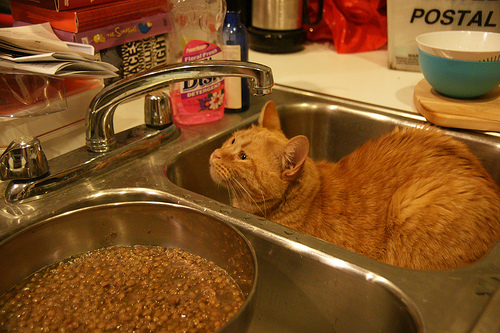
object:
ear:
[281, 134, 310, 181]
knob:
[0, 135, 49, 181]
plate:
[0, 199, 259, 333]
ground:
[408, 145, 460, 197]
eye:
[238, 150, 250, 160]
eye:
[231, 137, 236, 144]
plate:
[413, 30, 500, 99]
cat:
[208, 99, 500, 269]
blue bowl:
[415, 30, 500, 100]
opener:
[0, 136, 48, 182]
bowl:
[0, 201, 262, 333]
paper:
[0, 21, 121, 81]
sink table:
[0, 39, 500, 333]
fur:
[320, 146, 461, 235]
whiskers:
[212, 175, 265, 214]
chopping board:
[247, 42, 425, 115]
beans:
[83, 244, 169, 300]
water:
[0, 244, 241, 333]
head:
[209, 99, 309, 189]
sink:
[0, 186, 424, 333]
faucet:
[84, 59, 275, 153]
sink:
[163, 104, 500, 271]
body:
[266, 125, 500, 268]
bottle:
[165, 1, 228, 125]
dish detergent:
[167, 0, 225, 125]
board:
[412, 72, 500, 133]